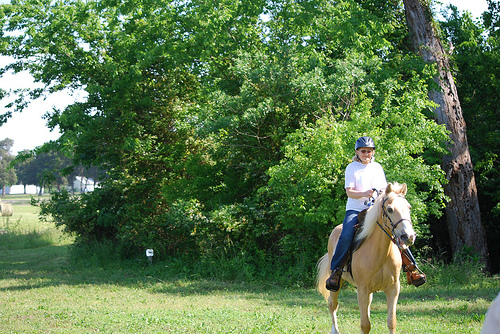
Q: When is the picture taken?
A: Daytime.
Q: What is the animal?
A: A horse.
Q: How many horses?
A: One.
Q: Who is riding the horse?
A: A person.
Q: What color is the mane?
A: White.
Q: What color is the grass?
A: Green.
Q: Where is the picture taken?
A: At a park.